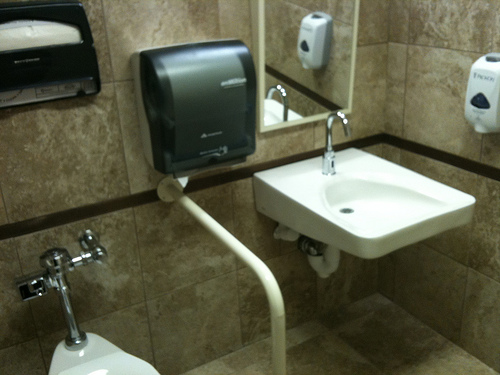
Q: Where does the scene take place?
A: In a bathroom.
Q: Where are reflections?
A: In the mirror.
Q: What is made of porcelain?
A: The sink.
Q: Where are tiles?
A: On the floor and wall.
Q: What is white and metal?
A: A pole.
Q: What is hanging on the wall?
A: A mirror.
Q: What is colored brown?
A: The tiles.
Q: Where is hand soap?
A: In a white container.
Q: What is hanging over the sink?
A: Mirror.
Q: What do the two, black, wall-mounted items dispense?
A: Paper towels and seat covers.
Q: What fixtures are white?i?
A: The toilet and the sink.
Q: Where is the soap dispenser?
A: On the wall, to the right of the sink.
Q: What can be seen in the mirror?
A: The wall, the stripe, the soap dispenser, the sink and the faucet.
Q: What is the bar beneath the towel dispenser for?
A: Handicap access.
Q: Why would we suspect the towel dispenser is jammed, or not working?
A: There is a roll of towels bunched between the handicap bar and he dispenser.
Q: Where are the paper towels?
A: To the left of the sink.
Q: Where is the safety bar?
A: The left of the sink.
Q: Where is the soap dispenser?
A: Right of the sink.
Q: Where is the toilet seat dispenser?
A: Above the toilet.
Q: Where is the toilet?
A: Left of the towel dispenser.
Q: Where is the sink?
A: Below the mirror.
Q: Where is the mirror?
A: Above the sink.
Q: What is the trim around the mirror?
A: White.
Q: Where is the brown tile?
A: On the wall and the floor.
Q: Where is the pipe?
A: Below the sink.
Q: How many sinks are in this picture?
A: One.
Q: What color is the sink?
A: White.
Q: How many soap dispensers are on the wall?
A: One.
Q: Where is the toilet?
A: On the ground.